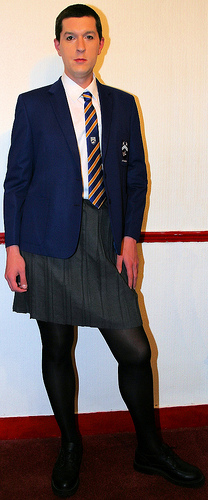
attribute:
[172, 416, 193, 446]
carpet — red 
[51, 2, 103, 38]
hair — short, black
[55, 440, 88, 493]
shoe — black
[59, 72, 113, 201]
shirt — white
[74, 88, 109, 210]
tie — blue, yellow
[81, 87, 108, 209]
tie — striped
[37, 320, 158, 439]
stockings — black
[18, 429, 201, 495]
carpet — maroon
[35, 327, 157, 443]
nylons — black 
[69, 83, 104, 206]
tie — blue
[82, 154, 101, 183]
stripes — yellow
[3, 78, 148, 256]
jacket — blue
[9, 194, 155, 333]
pleated skirt — gray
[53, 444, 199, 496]
shoes — black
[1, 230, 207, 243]
wood — Red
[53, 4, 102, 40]
hair — Black 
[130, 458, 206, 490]
sole — thick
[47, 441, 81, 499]
sole — thick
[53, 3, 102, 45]
hair — short, dark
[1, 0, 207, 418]
wall — light colored